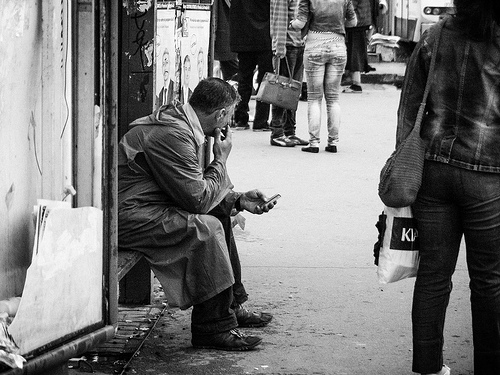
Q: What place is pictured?
A: It is a street.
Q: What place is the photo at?
A: It is at the street.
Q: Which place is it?
A: It is a street.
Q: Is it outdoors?
A: Yes, it is outdoors.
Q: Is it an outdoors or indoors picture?
A: It is outdoors.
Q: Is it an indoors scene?
A: No, it is outdoors.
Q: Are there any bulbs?
A: No, there are no bulbs.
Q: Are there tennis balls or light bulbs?
A: No, there are no light bulbs or tennis balls.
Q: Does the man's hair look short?
A: Yes, the hair is short.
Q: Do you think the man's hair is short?
A: Yes, the hair is short.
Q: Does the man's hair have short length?
A: Yes, the hair is short.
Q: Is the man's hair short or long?
A: The hair is short.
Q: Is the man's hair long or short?
A: The hair is short.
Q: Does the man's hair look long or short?
A: The hair is short.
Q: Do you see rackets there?
A: No, there are no rackets.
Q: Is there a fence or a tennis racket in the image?
A: No, there are no rackets or fences.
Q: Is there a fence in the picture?
A: No, there are no fences.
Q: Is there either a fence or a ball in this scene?
A: No, there are no fences or balls.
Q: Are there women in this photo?
A: Yes, there is a woman.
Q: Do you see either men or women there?
A: Yes, there is a woman.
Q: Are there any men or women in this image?
A: Yes, there is a woman.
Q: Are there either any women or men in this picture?
A: Yes, there is a woman.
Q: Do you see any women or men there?
A: Yes, there is a woman.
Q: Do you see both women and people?
A: Yes, there are both a woman and a person.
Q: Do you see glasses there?
A: No, there are no glasses.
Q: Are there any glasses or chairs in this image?
A: No, there are no glasses or chairs.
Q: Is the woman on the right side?
A: Yes, the woman is on the right of the image.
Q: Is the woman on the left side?
A: No, the woman is on the right of the image.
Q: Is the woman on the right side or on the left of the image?
A: The woman is on the right of the image.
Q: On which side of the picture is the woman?
A: The woman is on the right of the image.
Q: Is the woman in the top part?
A: Yes, the woman is in the top of the image.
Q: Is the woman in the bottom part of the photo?
A: No, the woman is in the top of the image.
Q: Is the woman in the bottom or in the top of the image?
A: The woman is in the top of the image.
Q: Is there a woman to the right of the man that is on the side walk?
A: Yes, there is a woman to the right of the man.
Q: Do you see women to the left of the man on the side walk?
A: No, the woman is to the right of the man.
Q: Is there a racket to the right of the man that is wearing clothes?
A: No, there is a woman to the right of the man.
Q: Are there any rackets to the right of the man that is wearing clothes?
A: No, there is a woman to the right of the man.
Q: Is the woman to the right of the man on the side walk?
A: Yes, the woman is to the right of the man.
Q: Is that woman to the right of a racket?
A: No, the woman is to the right of the man.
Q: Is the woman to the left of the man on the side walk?
A: No, the woman is to the right of the man.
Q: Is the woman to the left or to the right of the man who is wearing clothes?
A: The woman is to the right of the man.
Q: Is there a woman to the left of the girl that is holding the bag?
A: Yes, there is a woman to the left of the girl.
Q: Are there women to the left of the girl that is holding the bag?
A: Yes, there is a woman to the left of the girl.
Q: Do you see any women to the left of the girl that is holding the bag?
A: Yes, there is a woman to the left of the girl.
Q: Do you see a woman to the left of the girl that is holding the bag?
A: Yes, there is a woman to the left of the girl.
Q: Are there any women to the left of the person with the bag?
A: Yes, there is a woman to the left of the girl.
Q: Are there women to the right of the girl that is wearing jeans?
A: No, the woman is to the left of the girl.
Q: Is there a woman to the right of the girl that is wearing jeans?
A: No, the woman is to the left of the girl.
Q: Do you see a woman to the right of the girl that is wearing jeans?
A: No, the woman is to the left of the girl.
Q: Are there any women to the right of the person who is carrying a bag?
A: No, the woman is to the left of the girl.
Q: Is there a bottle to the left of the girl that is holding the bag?
A: No, there is a woman to the left of the girl.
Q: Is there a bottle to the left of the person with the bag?
A: No, there is a woman to the left of the girl.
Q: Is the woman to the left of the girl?
A: Yes, the woman is to the left of the girl.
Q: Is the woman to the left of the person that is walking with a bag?
A: Yes, the woman is to the left of the girl.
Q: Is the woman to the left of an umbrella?
A: No, the woman is to the left of the girl.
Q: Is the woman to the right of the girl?
A: No, the woman is to the left of the girl.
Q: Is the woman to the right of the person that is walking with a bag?
A: No, the woman is to the left of the girl.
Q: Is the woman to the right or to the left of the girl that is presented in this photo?
A: The woman is to the left of the girl.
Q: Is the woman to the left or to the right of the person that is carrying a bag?
A: The woman is to the left of the girl.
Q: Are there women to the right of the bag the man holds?
A: Yes, there is a woman to the right of the bag.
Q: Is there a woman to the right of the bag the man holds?
A: Yes, there is a woman to the right of the bag.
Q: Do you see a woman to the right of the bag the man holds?
A: Yes, there is a woman to the right of the bag.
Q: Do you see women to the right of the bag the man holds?
A: Yes, there is a woman to the right of the bag.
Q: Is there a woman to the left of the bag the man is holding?
A: No, the woman is to the right of the bag.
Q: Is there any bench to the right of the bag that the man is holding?
A: No, there is a woman to the right of the bag.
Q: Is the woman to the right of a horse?
A: No, the woman is to the right of a bag.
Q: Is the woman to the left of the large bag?
A: No, the woman is to the right of the bag.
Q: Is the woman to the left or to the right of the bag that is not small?
A: The woman is to the right of the bag.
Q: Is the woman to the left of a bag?
A: Yes, the woman is to the left of a bag.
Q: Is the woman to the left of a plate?
A: No, the woman is to the left of a bag.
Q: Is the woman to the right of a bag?
A: No, the woman is to the left of a bag.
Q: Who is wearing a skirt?
A: The woman is wearing a skirt.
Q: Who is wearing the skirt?
A: The woman is wearing a skirt.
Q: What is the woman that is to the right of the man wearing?
A: The woman is wearing a skirt.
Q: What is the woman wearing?
A: The woman is wearing a skirt.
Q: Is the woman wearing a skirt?
A: Yes, the woman is wearing a skirt.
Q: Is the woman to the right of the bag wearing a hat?
A: No, the woman is wearing a skirt.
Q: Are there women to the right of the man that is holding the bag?
A: Yes, there is a woman to the right of the man.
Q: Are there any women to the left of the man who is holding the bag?
A: No, the woman is to the right of the man.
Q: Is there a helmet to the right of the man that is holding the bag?
A: No, there is a woman to the right of the man.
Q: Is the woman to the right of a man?
A: Yes, the woman is to the right of a man.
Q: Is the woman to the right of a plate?
A: No, the woman is to the right of a man.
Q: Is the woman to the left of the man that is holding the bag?
A: No, the woman is to the right of the man.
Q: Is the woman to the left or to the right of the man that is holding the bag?
A: The woman is to the right of the man.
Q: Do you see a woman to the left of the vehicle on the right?
A: Yes, there is a woman to the left of the vehicle.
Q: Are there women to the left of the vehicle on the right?
A: Yes, there is a woman to the left of the vehicle.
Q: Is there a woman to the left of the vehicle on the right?
A: Yes, there is a woman to the left of the vehicle.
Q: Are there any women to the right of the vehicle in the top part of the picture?
A: No, the woman is to the left of the vehicle.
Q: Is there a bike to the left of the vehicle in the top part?
A: No, there is a woman to the left of the vehicle.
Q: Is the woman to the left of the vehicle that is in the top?
A: Yes, the woman is to the left of the vehicle.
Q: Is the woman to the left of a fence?
A: No, the woman is to the left of the vehicle.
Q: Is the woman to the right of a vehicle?
A: No, the woman is to the left of a vehicle.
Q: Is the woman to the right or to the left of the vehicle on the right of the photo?
A: The woman is to the left of the vehicle.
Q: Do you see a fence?
A: No, there are no fences.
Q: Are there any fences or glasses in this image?
A: No, there are no fences or glasses.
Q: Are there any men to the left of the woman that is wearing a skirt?
A: Yes, there is a man to the left of the woman.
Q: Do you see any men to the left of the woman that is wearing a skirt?
A: Yes, there is a man to the left of the woman.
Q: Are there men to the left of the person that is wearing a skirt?
A: Yes, there is a man to the left of the woman.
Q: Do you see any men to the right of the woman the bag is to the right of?
A: No, the man is to the left of the woman.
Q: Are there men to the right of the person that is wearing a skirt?
A: No, the man is to the left of the woman.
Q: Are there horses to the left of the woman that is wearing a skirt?
A: No, there is a man to the left of the woman.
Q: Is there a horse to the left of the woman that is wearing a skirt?
A: No, there is a man to the left of the woman.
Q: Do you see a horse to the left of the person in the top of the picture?
A: No, there is a man to the left of the woman.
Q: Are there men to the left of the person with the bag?
A: Yes, there is a man to the left of the girl.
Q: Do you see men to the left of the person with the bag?
A: Yes, there is a man to the left of the girl.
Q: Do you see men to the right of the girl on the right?
A: No, the man is to the left of the girl.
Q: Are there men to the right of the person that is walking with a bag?
A: No, the man is to the left of the girl.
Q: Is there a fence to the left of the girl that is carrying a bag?
A: No, there is a man to the left of the girl.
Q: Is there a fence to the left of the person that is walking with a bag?
A: No, there is a man to the left of the girl.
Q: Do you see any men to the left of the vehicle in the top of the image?
A: Yes, there is a man to the left of the vehicle.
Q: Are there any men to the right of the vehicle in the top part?
A: No, the man is to the left of the vehicle.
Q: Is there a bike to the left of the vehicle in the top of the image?
A: No, there is a man to the left of the vehicle.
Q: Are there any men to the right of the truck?
A: Yes, there is a man to the right of the truck.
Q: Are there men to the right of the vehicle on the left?
A: Yes, there is a man to the right of the truck.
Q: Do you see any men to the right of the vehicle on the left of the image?
A: Yes, there is a man to the right of the truck.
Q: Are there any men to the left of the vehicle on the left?
A: No, the man is to the right of the truck.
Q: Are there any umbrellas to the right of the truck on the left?
A: No, there is a man to the right of the truck.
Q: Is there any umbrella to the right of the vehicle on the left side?
A: No, there is a man to the right of the truck.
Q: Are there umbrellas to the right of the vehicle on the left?
A: No, there is a man to the right of the truck.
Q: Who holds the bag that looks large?
A: The man holds the bag.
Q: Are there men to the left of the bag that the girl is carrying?
A: Yes, there is a man to the left of the bag.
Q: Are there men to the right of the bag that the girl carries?
A: No, the man is to the left of the bag.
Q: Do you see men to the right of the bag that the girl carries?
A: No, the man is to the left of the bag.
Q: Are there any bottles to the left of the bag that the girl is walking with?
A: No, there is a man to the left of the bag.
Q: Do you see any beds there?
A: No, there are no beds.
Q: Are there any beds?
A: No, there are no beds.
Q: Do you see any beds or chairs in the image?
A: No, there are no beds or chairs.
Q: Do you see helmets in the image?
A: No, there are no helmets.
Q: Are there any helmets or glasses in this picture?
A: No, there are no helmets or glasses.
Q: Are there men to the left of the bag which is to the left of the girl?
A: Yes, there is a man to the left of the bag.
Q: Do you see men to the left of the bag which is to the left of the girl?
A: Yes, there is a man to the left of the bag.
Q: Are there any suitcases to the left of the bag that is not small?
A: No, there is a man to the left of the bag.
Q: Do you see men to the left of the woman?
A: Yes, there is a man to the left of the woman.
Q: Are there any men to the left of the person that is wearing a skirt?
A: Yes, there is a man to the left of the woman.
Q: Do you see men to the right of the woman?
A: No, the man is to the left of the woman.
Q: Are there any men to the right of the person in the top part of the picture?
A: No, the man is to the left of the woman.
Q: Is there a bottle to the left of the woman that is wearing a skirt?
A: No, there is a man to the left of the woman.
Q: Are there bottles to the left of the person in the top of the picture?
A: No, there is a man to the left of the woman.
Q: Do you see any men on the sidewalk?
A: Yes, there is a man on the sidewalk.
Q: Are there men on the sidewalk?
A: Yes, there is a man on the sidewalk.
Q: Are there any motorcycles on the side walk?
A: No, there is a man on the side walk.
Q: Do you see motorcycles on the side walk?
A: No, there is a man on the side walk.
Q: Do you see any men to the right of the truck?
A: Yes, there is a man to the right of the truck.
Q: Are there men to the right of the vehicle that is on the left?
A: Yes, there is a man to the right of the truck.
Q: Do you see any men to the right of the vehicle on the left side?
A: Yes, there is a man to the right of the truck.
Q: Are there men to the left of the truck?
A: No, the man is to the right of the truck.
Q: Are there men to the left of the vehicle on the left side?
A: No, the man is to the right of the truck.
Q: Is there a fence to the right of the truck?
A: No, there is a man to the right of the truck.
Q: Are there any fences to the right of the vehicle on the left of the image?
A: No, there is a man to the right of the truck.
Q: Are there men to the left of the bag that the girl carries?
A: Yes, there is a man to the left of the bag.